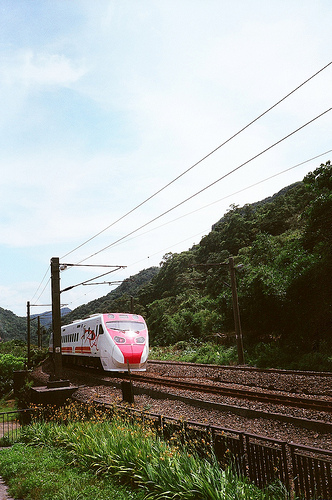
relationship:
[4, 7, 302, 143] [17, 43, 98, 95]
sky with clouds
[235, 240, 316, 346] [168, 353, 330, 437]
tree beside track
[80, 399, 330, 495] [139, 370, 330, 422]
fence along side rail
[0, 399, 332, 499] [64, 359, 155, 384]
fence along side rail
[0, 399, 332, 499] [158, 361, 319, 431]
fence running along tracks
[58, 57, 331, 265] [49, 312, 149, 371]
electrical wire over rail train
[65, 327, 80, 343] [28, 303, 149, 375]
passenger window on train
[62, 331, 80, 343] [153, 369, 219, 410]
passenger window on rail train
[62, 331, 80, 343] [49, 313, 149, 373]
passenger window on train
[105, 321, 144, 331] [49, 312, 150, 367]
window on rail train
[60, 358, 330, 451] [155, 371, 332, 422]
gravel on rail train